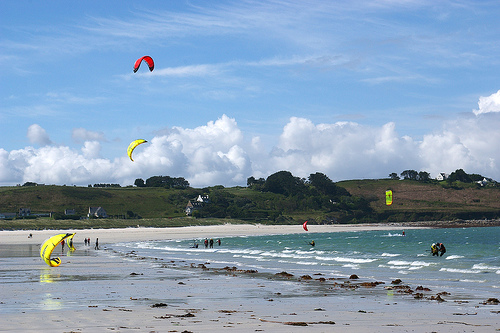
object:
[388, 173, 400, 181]
trees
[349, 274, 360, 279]
rock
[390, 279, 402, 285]
rock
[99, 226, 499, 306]
shoreline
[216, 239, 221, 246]
people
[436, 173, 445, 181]
house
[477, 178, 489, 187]
house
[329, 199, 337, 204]
house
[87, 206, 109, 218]
house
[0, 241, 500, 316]
water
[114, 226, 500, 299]
ocean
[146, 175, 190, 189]
trees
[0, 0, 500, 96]
thin clouds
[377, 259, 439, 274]
wave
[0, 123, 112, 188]
clouds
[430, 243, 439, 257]
people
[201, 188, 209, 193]
trees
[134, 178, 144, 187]
trees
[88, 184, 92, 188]
trees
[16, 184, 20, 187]
trees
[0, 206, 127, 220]
building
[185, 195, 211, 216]
house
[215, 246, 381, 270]
waves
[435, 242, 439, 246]
cap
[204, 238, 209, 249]
people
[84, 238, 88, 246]
people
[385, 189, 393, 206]
glider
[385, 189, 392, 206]
yellow green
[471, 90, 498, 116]
cloud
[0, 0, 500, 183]
sky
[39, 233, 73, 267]
glider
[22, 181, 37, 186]
trees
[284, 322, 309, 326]
seaweed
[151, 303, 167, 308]
seaweed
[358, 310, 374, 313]
seaweed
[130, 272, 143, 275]
seaweed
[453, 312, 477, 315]
seaweed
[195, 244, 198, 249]
people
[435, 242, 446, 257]
people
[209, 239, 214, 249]
people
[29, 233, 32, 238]
people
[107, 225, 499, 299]
water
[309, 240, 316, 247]
person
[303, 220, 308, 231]
sail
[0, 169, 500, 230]
hill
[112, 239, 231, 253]
waves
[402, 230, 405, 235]
person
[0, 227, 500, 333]
sand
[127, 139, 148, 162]
black glider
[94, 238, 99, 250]
people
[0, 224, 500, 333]
shore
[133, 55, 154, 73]
kite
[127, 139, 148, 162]
kite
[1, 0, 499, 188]
air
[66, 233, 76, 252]
parasail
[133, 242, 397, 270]
surf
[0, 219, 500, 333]
beach